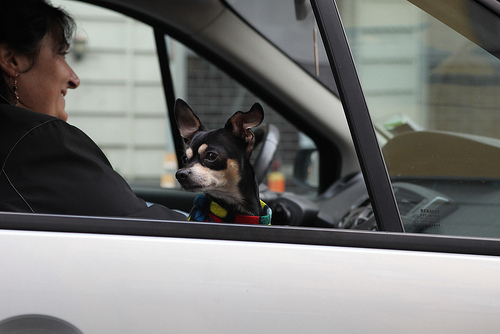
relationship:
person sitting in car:
[0, 1, 189, 221] [1, 0, 481, 331]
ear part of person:
[0, 43, 23, 80] [0, 1, 189, 221]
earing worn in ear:
[11, 72, 23, 105] [0, 43, 23, 80]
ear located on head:
[172, 98, 209, 146] [148, 124, 316, 202]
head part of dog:
[148, 124, 316, 202] [178, 100, 308, 208]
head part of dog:
[173, 97, 265, 193] [173, 99, 273, 224]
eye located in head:
[182, 154, 187, 162] [173, 97, 265, 193]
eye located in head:
[202, 151, 220, 162] [173, 97, 265, 193]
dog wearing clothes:
[173, 99, 273, 224] [183, 190, 272, 223]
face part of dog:
[187, 135, 239, 186] [173, 99, 273, 224]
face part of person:
[7, 37, 78, 123] [0, 1, 189, 221]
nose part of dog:
[173, 170, 190, 182] [173, 99, 273, 224]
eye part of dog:
[202, 148, 217, 162] [155, 87, 290, 221]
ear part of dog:
[170, 97, 210, 148] [173, 99, 273, 224]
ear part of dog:
[223, 101, 265, 160] [173, 99, 273, 224]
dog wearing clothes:
[173, 97, 265, 223] [207, 198, 271, 222]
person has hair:
[0, 1, 185, 212] [3, 3, 76, 113]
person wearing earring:
[0, 1, 185, 212] [9, 54, 28, 104]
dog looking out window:
[173, 99, 273, 224] [1, 1, 385, 230]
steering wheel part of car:
[247, 120, 281, 185] [1, 0, 481, 331]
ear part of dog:
[223, 98, 265, 155] [173, 99, 273, 224]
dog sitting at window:
[173, 99, 273, 224] [1, 1, 385, 230]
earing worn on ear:
[13, 72, 22, 107] [220, 79, 275, 158]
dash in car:
[314, 173, 469, 234] [1, 0, 481, 331]